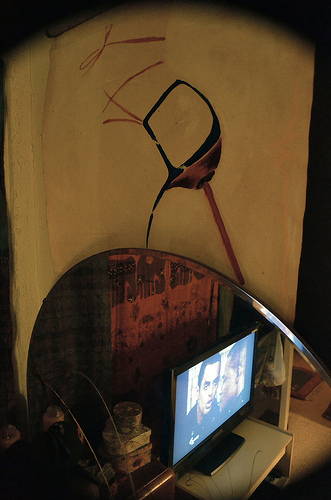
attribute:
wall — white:
[0, 0, 330, 414]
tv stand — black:
[176, 428, 241, 477]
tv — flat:
[162, 309, 282, 472]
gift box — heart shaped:
[103, 414, 150, 455]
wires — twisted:
[30, 363, 136, 499]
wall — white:
[3, 121, 129, 247]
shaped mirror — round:
[47, 270, 317, 433]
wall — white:
[7, 10, 329, 387]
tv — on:
[166, 331, 255, 471]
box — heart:
[100, 416, 150, 453]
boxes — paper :
[94, 391, 155, 473]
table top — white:
[172, 412, 297, 498]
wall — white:
[57, 137, 113, 211]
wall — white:
[35, 100, 88, 217]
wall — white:
[2, 2, 308, 318]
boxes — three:
[107, 401, 145, 429]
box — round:
[106, 426, 151, 455]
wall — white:
[6, 3, 319, 461]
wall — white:
[6, 9, 320, 234]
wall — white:
[233, 44, 298, 223]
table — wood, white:
[251, 445, 261, 457]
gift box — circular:
[113, 400, 142, 435]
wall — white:
[70, 133, 108, 187]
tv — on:
[151, 316, 274, 497]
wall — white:
[9, 6, 310, 247]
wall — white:
[48, 151, 130, 228]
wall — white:
[47, 101, 136, 209]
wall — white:
[56, 95, 237, 229]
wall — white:
[59, 75, 184, 180]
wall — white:
[45, 60, 227, 180]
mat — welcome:
[286, 357, 320, 413]